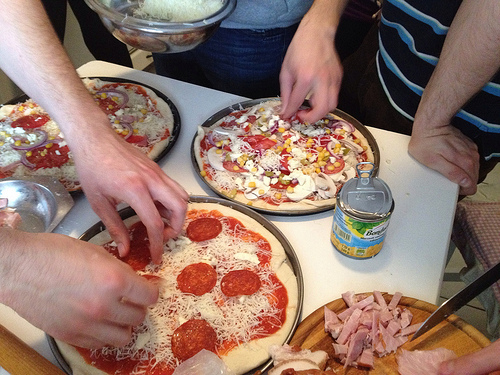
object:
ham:
[343, 332, 368, 373]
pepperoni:
[175, 263, 218, 298]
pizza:
[53, 202, 295, 375]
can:
[332, 180, 395, 261]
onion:
[95, 85, 130, 117]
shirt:
[376, 1, 499, 164]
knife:
[408, 263, 498, 347]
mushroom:
[313, 171, 337, 198]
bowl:
[83, 0, 237, 55]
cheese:
[140, 1, 225, 22]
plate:
[289, 293, 495, 374]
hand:
[72, 130, 189, 264]